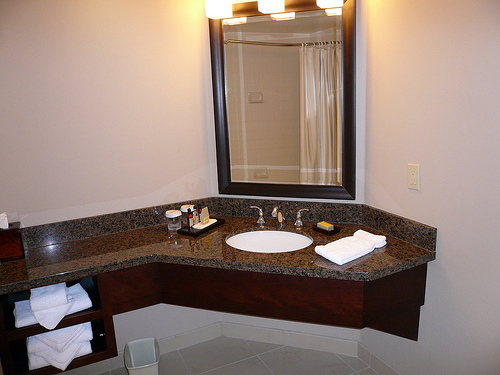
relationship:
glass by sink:
[163, 208, 180, 230] [225, 228, 316, 253]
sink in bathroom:
[225, 228, 316, 253] [3, 0, 496, 372]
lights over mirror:
[197, 1, 386, 23] [202, 9, 375, 210]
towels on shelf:
[25, 322, 98, 371] [9, 265, 122, 367]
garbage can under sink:
[125, 337, 161, 373] [222, 225, 312, 252]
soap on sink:
[316, 221, 334, 231] [221, 225, 315, 255]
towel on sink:
[314, 229, 387, 266] [241, 187, 328, 250]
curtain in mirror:
[285, 30, 352, 190] [222, 14, 361, 199]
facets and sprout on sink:
[185, 200, 373, 241] [192, 210, 320, 260]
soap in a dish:
[318, 222, 333, 228] [312, 225, 342, 232]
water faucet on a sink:
[266, 199, 288, 229] [215, 206, 322, 254]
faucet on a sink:
[249, 206, 265, 224] [215, 191, 317, 266]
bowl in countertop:
[215, 219, 316, 260] [1, 218, 435, 310]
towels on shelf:
[13, 281, 92, 371] [6, 268, 122, 373]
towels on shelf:
[29, 278, 78, 332] [6, 268, 122, 373]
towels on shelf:
[25, 323, 96, 371] [6, 268, 122, 373]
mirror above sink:
[209, 10, 358, 200] [225, 228, 316, 253]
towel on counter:
[317, 219, 392, 270] [3, 215, 432, 295]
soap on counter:
[316, 221, 334, 231] [3, 215, 432, 295]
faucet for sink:
[250, 200, 265, 222] [223, 222, 315, 260]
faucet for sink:
[291, 204, 311, 233] [223, 222, 315, 260]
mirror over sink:
[209, 10, 358, 200] [222, 225, 312, 252]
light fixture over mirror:
[202, 2, 244, 30] [198, 15, 363, 207]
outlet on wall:
[390, 161, 435, 196] [205, 1, 484, 352]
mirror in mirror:
[220, 14, 346, 187] [203, 1, 362, 201]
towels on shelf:
[29, 282, 74, 329] [6, 268, 122, 373]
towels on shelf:
[12, 282, 95, 329] [6, 268, 122, 373]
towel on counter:
[314, 229, 387, 266] [0, 216, 437, 295]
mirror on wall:
[220, 14, 346, 187] [205, 1, 484, 352]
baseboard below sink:
[84, 311, 392, 372] [220, 210, 327, 264]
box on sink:
[3, 214, 35, 269] [226, 195, 332, 264]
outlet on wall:
[407, 164, 420, 191] [2, 4, 498, 372]